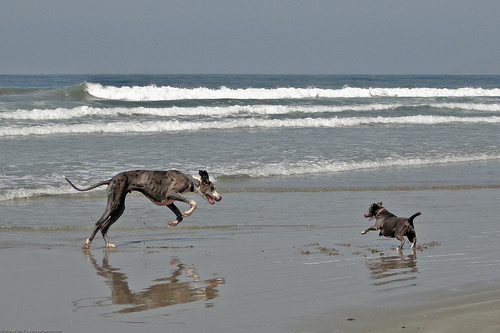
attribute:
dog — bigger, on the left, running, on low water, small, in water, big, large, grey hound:
[61, 162, 224, 255]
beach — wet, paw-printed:
[6, 75, 498, 332]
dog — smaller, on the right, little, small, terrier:
[359, 200, 422, 254]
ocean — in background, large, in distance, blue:
[1, 81, 496, 197]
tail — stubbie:
[410, 211, 420, 221]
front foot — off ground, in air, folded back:
[169, 215, 185, 230]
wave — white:
[84, 80, 500, 102]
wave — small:
[3, 100, 500, 116]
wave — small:
[1, 114, 500, 129]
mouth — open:
[205, 192, 219, 205]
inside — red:
[207, 195, 215, 203]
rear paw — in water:
[82, 223, 98, 251]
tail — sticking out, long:
[64, 172, 110, 198]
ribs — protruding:
[138, 173, 167, 195]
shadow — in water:
[78, 243, 226, 315]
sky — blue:
[0, 3, 498, 79]